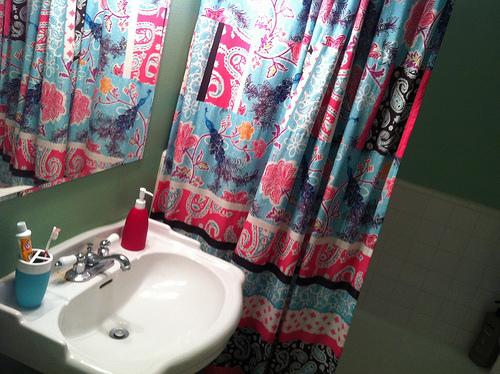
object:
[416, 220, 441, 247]
tile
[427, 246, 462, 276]
tile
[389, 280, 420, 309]
tile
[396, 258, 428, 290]
tile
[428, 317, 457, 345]
tile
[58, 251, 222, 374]
sink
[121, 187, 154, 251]
soap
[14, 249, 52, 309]
holder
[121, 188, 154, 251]
bottle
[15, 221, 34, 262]
toothpaste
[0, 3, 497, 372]
bathroom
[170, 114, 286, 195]
pattern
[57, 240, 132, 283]
faucet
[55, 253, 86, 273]
handles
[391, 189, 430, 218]
tiles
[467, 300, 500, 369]
bottle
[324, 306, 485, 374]
bathtub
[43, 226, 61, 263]
toothbrush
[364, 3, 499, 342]
bathroom wall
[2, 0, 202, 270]
wall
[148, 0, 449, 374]
curtain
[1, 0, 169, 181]
reflection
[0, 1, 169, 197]
mirror